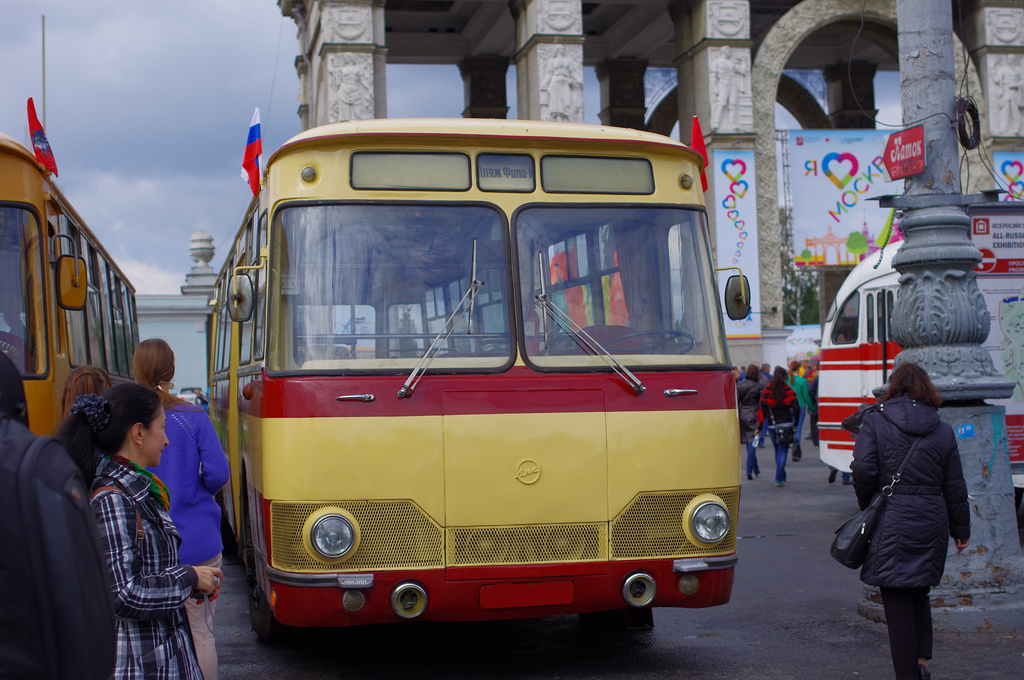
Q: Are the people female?
A: Yes, all the people are female.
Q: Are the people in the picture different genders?
A: No, all the people are female.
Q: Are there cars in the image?
A: No, there are no cars.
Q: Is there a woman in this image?
A: Yes, there are women.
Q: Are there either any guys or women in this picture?
A: Yes, there are women.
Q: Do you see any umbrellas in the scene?
A: No, there are no umbrellas.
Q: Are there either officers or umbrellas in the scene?
A: No, there are no umbrellas or officers.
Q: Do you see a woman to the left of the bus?
A: Yes, there are women to the left of the bus.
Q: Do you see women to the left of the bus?
A: Yes, there are women to the left of the bus.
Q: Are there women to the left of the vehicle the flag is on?
A: Yes, there are women to the left of the bus.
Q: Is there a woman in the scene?
A: Yes, there are women.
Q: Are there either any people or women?
A: Yes, there are women.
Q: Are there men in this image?
A: No, there are no men.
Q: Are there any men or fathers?
A: No, there are no men or fathers.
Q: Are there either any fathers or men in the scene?
A: No, there are no men or fathers.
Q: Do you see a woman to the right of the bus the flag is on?
A: Yes, there are women to the right of the bus.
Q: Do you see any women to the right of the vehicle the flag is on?
A: Yes, there are women to the right of the bus.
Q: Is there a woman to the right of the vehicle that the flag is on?
A: Yes, there are women to the right of the bus.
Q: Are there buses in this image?
A: Yes, there is a bus.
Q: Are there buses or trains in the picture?
A: Yes, there is a bus.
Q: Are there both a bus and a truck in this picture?
A: No, there is a bus but no trucks.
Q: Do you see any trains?
A: No, there are no trains.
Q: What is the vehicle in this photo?
A: The vehicle is a bus.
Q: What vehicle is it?
A: The vehicle is a bus.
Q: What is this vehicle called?
A: This is a bus.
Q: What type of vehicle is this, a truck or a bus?
A: This is a bus.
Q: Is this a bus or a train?
A: This is a bus.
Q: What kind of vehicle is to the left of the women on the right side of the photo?
A: The vehicle is a bus.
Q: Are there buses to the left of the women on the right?
A: Yes, there is a bus to the left of the women.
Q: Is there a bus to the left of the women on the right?
A: Yes, there is a bus to the left of the women.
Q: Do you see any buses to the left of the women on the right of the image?
A: Yes, there is a bus to the left of the women.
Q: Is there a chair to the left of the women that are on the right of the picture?
A: No, there is a bus to the left of the women.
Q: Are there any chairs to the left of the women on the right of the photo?
A: No, there is a bus to the left of the women.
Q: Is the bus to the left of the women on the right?
A: Yes, the bus is to the left of the women.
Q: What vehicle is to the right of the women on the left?
A: The vehicle is a bus.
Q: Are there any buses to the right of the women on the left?
A: Yes, there is a bus to the right of the women.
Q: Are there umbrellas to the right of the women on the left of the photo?
A: No, there is a bus to the right of the women.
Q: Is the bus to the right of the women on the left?
A: Yes, the bus is to the right of the women.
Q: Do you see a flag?
A: Yes, there is a flag.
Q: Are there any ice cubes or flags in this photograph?
A: Yes, there is a flag.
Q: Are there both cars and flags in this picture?
A: No, there is a flag but no cars.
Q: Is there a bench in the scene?
A: No, there are no benches.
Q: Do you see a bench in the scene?
A: No, there are no benches.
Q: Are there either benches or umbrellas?
A: No, there are no benches or umbrellas.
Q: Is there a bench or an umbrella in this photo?
A: No, there are no benches or umbrellas.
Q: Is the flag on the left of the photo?
A: Yes, the flag is on the left of the image.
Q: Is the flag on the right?
A: No, the flag is on the left of the image.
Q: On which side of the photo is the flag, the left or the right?
A: The flag is on the left of the image.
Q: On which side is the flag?
A: The flag is on the left of the image.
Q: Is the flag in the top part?
A: Yes, the flag is in the top of the image.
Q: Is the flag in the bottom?
A: No, the flag is in the top of the image.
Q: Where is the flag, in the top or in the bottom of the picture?
A: The flag is in the top of the image.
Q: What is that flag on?
A: The flag is on the bus.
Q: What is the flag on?
A: The flag is on the bus.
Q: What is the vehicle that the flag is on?
A: The vehicle is a bus.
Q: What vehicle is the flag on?
A: The flag is on the bus.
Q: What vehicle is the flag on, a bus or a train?
A: The flag is on a bus.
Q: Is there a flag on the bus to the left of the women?
A: Yes, there is a flag on the bus.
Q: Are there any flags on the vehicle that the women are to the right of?
A: Yes, there is a flag on the bus.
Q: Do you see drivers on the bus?
A: No, there is a flag on the bus.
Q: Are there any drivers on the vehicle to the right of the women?
A: No, there is a flag on the bus.